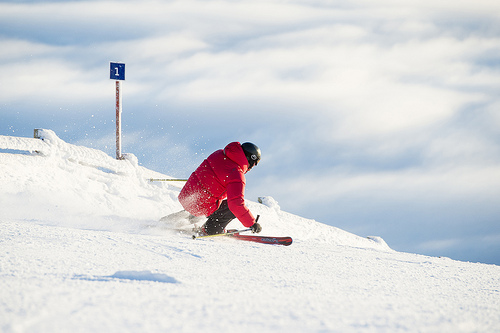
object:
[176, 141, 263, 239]
man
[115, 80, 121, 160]
post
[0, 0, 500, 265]
sky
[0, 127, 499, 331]
mountain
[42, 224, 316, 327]
snow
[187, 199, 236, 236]
pants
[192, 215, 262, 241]
pole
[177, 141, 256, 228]
coat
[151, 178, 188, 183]
poles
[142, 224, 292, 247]
ski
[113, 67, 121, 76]
1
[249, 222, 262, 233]
hand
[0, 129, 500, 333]
ground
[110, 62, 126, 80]
square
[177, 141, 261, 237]
person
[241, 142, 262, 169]
helmet